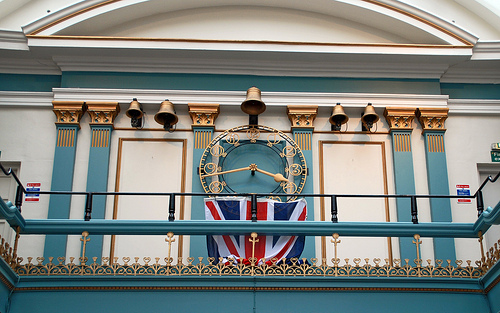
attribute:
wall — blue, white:
[46, 121, 460, 221]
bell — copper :
[153, 96, 182, 128]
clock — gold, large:
[199, 124, 307, 200]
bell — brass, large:
[122, 96, 147, 125]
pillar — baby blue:
[38, 120, 77, 262]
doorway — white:
[2, 159, 20, 249]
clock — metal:
[189, 108, 312, 205]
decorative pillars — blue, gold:
[42, 99, 459, 267]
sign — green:
[464, 136, 496, 163]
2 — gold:
[281, 144, 295, 158]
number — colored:
[169, 94, 295, 208]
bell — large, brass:
[326, 104, 347, 124]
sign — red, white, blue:
[452, 180, 474, 207]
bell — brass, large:
[240, 85, 262, 120]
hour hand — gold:
[243, 160, 294, 188]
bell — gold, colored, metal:
[231, 91, 261, 122]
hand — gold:
[191, 161, 252, 182]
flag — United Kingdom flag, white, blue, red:
[203, 196, 307, 263]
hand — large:
[200, 157, 249, 181]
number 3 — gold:
[283, 160, 309, 178]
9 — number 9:
[213, 141, 231, 159]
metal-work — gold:
[198, 153, 223, 173]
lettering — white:
[464, 134, 484, 172]